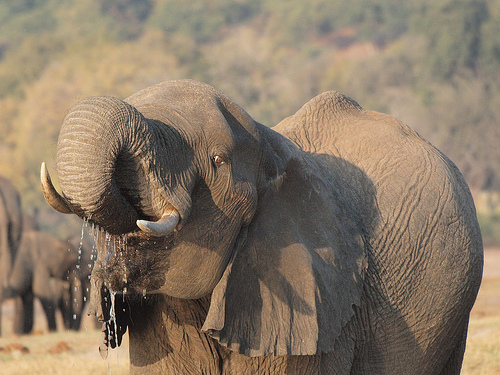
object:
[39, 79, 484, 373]
elephant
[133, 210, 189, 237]
tusk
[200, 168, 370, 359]
ear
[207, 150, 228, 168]
eye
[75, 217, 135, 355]
water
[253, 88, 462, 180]
back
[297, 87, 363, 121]
hump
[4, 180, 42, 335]
elephants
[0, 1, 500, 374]
background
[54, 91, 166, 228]
trunk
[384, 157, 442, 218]
skin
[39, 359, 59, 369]
grass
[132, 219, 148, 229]
tip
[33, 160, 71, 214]
tusk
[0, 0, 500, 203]
hillside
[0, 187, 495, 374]
field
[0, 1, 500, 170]
trees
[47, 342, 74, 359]
feces